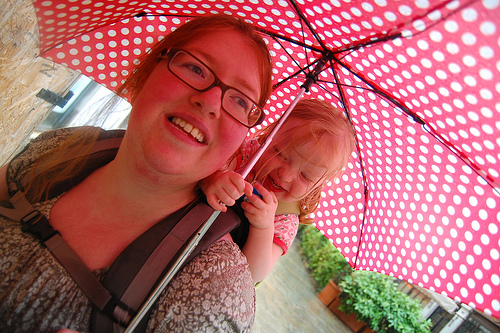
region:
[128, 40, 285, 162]
the glasses are dark colored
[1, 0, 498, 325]
two people under an umbrella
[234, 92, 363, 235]
the little girl is smiling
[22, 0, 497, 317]
the umbrella is polka dot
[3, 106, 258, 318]
the woman has straps on her shoulders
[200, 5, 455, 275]
the little girl is holding the umbrella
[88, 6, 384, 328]
the little girl is on the woman's back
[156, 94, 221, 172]
the woman has teeth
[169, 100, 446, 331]
bushes behind the people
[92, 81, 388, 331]
the umbrella pole is silver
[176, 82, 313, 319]
handel for the umbrella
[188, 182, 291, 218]
hand's of the little girl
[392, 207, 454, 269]
polkadot's on the umbrella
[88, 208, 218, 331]
strap of the backpack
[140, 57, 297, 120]
glasses on the woman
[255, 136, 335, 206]
face of the little girl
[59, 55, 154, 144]
hair from the woman's head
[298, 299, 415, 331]
plant's in the background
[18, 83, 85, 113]
hinge on the gate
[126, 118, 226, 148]
teeth in the woman's mouth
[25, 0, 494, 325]
an open umbrella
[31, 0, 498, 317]
a red and white polka dotted umbrella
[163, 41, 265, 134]
a pair of glasses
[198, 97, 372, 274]
a young girl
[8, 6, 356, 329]
a mother carrying child on back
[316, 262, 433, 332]
a potted green plant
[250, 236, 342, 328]
a brick paved sidewalk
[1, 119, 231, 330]
a black carrier harness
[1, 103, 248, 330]
a brown and white blouse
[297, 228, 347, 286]
a green trimmed hedge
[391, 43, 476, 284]
red polka dotted umbrella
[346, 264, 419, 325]
green leaves of a potted plant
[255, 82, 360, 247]
little girl on lady's back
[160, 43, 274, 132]
black glasses on a woman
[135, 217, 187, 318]
strap on a woman's shoulder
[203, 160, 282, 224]
hands of a little girl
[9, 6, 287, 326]
woman holding an umbrella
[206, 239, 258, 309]
shoulder of a woman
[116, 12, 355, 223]
woman and child under umbrella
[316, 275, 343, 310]
terra cotta planter on the ground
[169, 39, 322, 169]
Glasses on woman's face.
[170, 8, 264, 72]
Woman has red hair.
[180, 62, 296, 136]
Woman has blue eyes.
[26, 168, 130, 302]
Brown straps on woman's chest.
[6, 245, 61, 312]
Woman wearing printed shirt.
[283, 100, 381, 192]
Girl has blonde hair.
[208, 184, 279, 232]
Girl holding umbrella.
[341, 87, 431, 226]
Umbrella is red with white polka dots.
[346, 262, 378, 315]
Green plants in pots in background.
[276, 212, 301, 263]
Girl wearing pink shirt.